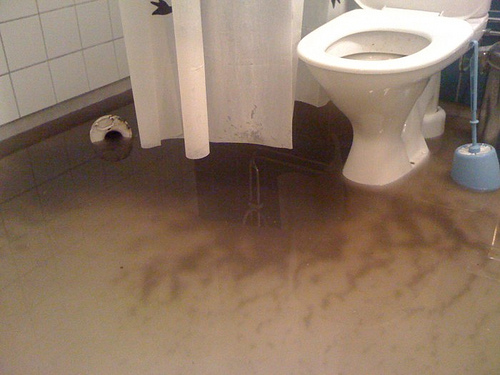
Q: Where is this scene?
A: Bathroom.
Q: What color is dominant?
A: White.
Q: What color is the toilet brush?
A: Blue.